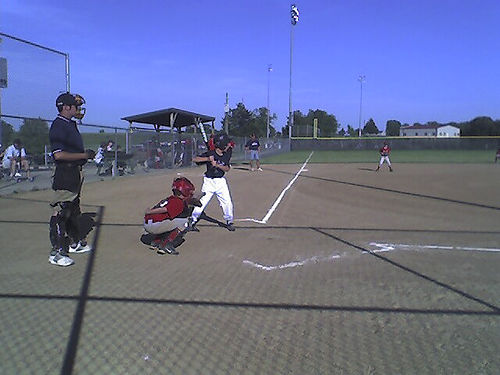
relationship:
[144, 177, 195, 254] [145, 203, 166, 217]
boy has hand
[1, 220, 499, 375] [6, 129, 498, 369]
shadow on ground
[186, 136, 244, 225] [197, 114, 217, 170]
boy holding bat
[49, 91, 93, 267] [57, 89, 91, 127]
umpire wearing a face mask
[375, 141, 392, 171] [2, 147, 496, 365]
player on field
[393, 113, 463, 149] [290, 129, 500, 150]
buildings behind fence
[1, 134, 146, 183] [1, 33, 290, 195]
people standing behind fence